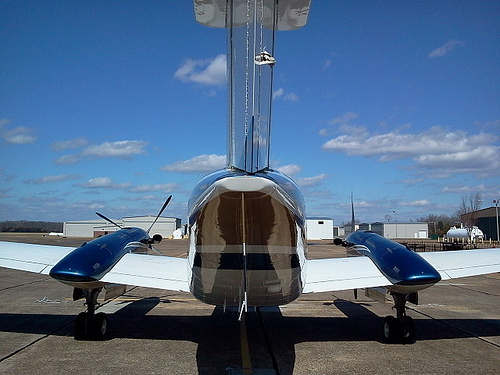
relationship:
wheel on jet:
[90, 311, 110, 341] [0, 1, 499, 339]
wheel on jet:
[74, 311, 90, 341] [0, 1, 499, 339]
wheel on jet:
[379, 316, 400, 344] [0, 1, 499, 339]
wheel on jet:
[401, 315, 418, 344] [0, 1, 499, 339]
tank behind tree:
[445, 225, 484, 240] [455, 192, 485, 242]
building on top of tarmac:
[62, 216, 181, 239] [0, 232, 499, 374]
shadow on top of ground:
[1, 296, 499, 373] [0, 232, 499, 374]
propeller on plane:
[95, 212, 124, 230] [0, 1, 499, 339]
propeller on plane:
[145, 195, 173, 236] [0, 1, 499, 339]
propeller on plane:
[148, 244, 163, 254] [0, 1, 499, 339]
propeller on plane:
[354, 287, 360, 299] [0, 1, 499, 339]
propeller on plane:
[304, 240, 345, 247] [0, 1, 499, 339]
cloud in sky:
[167, 52, 230, 98] [1, 0, 499, 226]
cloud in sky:
[156, 154, 229, 174] [1, 0, 499, 226]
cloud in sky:
[78, 137, 148, 162] [1, 0, 499, 226]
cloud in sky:
[46, 136, 90, 152] [1, 0, 499, 226]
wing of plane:
[0, 240, 190, 293] [0, 1, 499, 339]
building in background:
[62, 216, 181, 239] [1, 0, 498, 241]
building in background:
[372, 221, 430, 242] [1, 0, 498, 241]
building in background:
[305, 217, 334, 241] [1, 0, 498, 241]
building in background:
[460, 207, 500, 246] [1, 0, 498, 241]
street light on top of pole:
[490, 198, 498, 205] [496, 210, 500, 241]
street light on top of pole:
[497, 200, 500, 203] [496, 210, 500, 241]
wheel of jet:
[90, 311, 110, 341] [0, 1, 499, 339]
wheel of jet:
[379, 316, 400, 344] [0, 1, 499, 339]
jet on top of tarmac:
[0, 1, 499, 339] [0, 232, 499, 374]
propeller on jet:
[95, 212, 124, 230] [0, 1, 499, 339]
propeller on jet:
[145, 195, 173, 236] [0, 1, 499, 339]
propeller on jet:
[148, 244, 163, 254] [0, 1, 499, 339]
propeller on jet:
[304, 240, 345, 247] [0, 1, 499, 339]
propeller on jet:
[354, 287, 360, 299] [0, 1, 499, 339]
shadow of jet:
[1, 296, 499, 373] [0, 1, 499, 339]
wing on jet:
[0, 240, 190, 293] [0, 1, 499, 339]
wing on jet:
[304, 248, 500, 294] [0, 1, 499, 339]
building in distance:
[62, 216, 181, 239] [1, 0, 498, 241]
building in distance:
[305, 217, 334, 241] [1, 0, 498, 241]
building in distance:
[372, 221, 430, 242] [1, 0, 498, 241]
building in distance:
[460, 207, 500, 246] [1, 0, 498, 241]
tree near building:
[455, 192, 485, 242] [460, 207, 500, 246]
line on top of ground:
[239, 294, 254, 374] [0, 232, 499, 374]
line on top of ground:
[62, 296, 203, 303] [0, 232, 499, 374]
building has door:
[372, 221, 430, 242] [419, 229, 429, 239]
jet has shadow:
[0, 1, 499, 339] [1, 296, 499, 373]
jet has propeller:
[0, 1, 499, 339] [95, 212, 124, 230]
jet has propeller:
[0, 1, 499, 339] [145, 195, 173, 236]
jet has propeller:
[0, 1, 499, 339] [148, 244, 163, 254]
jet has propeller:
[0, 1, 499, 339] [304, 240, 345, 247]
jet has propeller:
[0, 1, 499, 339] [354, 287, 360, 299]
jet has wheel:
[0, 1, 499, 339] [90, 311, 110, 341]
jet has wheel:
[0, 1, 499, 339] [74, 311, 90, 341]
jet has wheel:
[0, 1, 499, 339] [401, 315, 418, 344]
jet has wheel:
[0, 1, 499, 339] [379, 316, 400, 344]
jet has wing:
[0, 1, 499, 339] [0, 240, 190, 293]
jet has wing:
[0, 1, 499, 339] [304, 248, 500, 294]